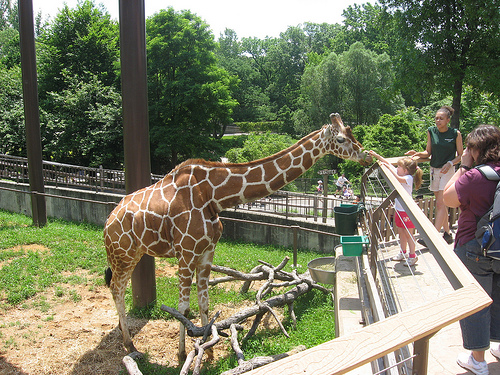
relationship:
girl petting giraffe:
[366, 142, 431, 268] [92, 107, 374, 352]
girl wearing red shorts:
[366, 142, 431, 268] [390, 208, 414, 231]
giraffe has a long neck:
[92, 107, 374, 352] [198, 108, 322, 207]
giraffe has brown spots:
[92, 107, 374, 352] [164, 194, 202, 247]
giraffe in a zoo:
[92, 107, 374, 352] [5, 3, 481, 362]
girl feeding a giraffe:
[366, 142, 431, 268] [92, 107, 374, 352]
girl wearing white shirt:
[366, 142, 431, 268] [394, 171, 418, 212]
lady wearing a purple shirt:
[440, 123, 500, 374] [453, 163, 497, 245]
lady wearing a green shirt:
[440, 123, 500, 374] [425, 129, 456, 165]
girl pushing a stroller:
[366, 149, 421, 267] [346, 185, 357, 200]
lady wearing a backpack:
[440, 123, 500, 374] [477, 180, 499, 267]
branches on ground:
[162, 249, 319, 374] [31, 248, 125, 373]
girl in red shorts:
[366, 142, 431, 268] [390, 208, 414, 231]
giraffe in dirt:
[92, 107, 374, 352] [66, 311, 162, 374]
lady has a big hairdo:
[457, 145, 499, 273] [467, 122, 497, 168]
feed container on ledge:
[336, 191, 368, 273] [361, 165, 417, 264]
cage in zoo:
[31, 147, 471, 363] [5, 3, 481, 362]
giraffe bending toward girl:
[92, 107, 374, 352] [366, 149, 421, 267]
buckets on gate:
[321, 175, 384, 295] [378, 229, 418, 246]